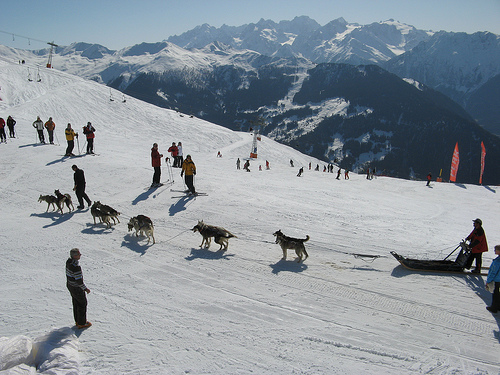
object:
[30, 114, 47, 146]
person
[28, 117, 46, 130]
top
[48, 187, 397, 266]
ropes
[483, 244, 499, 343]
person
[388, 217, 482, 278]
dog sled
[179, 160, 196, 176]
jacket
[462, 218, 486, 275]
man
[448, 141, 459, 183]
flag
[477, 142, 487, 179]
flag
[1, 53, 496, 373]
slope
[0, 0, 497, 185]
mountains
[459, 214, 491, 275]
person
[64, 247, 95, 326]
person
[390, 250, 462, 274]
sled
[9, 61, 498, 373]
snow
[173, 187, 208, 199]
skis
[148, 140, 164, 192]
people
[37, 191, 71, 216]
animals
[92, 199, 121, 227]
animals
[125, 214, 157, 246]
animals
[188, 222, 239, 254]
animals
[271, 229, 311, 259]
animals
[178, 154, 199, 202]
people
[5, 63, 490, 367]
ground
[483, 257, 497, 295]
jacket